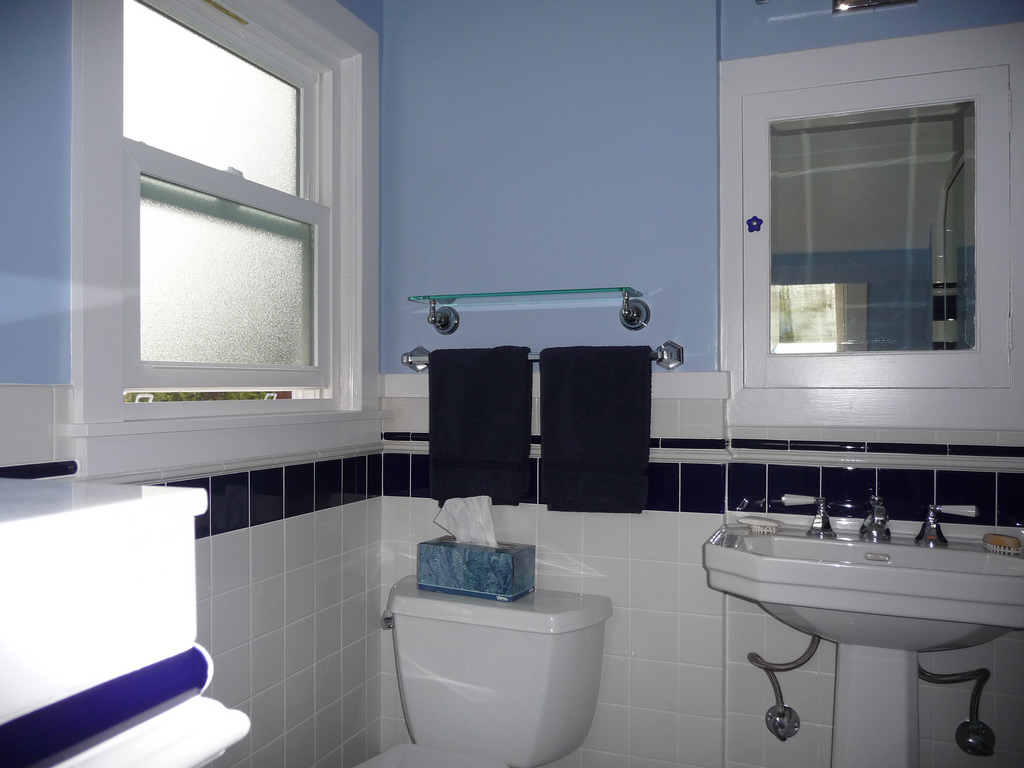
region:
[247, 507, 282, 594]
a tree in the woods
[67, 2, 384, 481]
White window in bathroom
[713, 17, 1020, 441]
Medicine cabinet with mirror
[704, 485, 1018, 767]
Stand up sink underneath medicine cabinet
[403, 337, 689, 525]
Towel rack with blue towels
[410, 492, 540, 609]
Blue kleenex box on top of toilet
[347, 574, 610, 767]
White toilet against wall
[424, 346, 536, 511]
Blue hand towel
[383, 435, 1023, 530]
Row of blue tiles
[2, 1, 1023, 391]
Light blue painted wall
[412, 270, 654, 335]
a glass shelf on a wall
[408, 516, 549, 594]
a box of tissue on a toilet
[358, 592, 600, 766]
a white toilet bowl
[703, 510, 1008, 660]
a white bathroom sink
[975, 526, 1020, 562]
a bar of soap on a sink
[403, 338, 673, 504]
two towels hanging on a towel rack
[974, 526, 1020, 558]
a bar of soap on a soap dish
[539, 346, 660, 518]
a black towel hanging on a rack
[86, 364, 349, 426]
a window partially opened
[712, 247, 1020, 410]
a mirror on the wall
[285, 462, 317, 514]
shiny tile is in a bathroom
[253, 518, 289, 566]
shiny tile is in a bathroom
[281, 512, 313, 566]
shiny tile is in a bathroom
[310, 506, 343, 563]
shiny tile is in a bathroom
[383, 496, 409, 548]
shiny tile is in a bathroom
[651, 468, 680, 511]
shiny tile is in a bathroom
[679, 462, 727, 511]
shiny tile is in a bathroom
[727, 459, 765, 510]
shiny tile is in a bathroom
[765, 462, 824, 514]
shiny tile is in a bathroom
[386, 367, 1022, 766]
the bathroom wall is tiled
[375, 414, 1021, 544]
blue tiles form a border on the wall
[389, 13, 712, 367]
the top half of the wall is painted blue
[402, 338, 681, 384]
there is a towel bar under the shelf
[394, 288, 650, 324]
a shelf is fastened to the wall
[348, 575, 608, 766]
the toilet is underneath the shelf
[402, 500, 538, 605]
there is a box of tissue on top of the toilet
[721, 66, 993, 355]
there is a mirror in the center of the medicine cabinet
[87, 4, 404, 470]
a window is located next to the toilet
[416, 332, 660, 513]
black towels above the toilet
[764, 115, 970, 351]
mirror above the sink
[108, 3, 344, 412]
window beside the toilet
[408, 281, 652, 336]
glass shelf above the toilet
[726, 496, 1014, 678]
white sink on the wall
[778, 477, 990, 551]
knobs on the sink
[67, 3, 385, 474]
white frame of the window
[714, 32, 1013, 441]
white frame around the mirror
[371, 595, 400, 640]
handle on a toilet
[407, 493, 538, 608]
a box of tissues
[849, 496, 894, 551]
faucet on a sink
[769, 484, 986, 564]
pair of sink handles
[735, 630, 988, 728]
pipes under a sink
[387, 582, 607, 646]
lid on a toilet tank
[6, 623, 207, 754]
a blue plastic bar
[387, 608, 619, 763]
back of a toilet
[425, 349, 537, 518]
a large black towel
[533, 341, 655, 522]
a large black towel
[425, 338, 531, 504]
a large black towel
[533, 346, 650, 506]
a large black towel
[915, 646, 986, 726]
pipe under the sink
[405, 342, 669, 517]
two black towels hanging on the rack